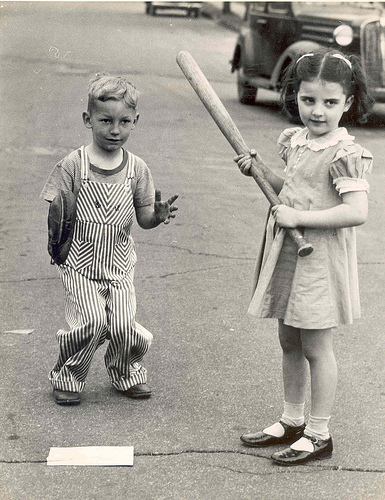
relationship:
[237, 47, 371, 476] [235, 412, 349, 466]
girl wearing shoes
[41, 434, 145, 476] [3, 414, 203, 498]
paper on pavement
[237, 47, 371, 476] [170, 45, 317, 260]
girl holding bat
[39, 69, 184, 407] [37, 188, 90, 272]
boy holding mitt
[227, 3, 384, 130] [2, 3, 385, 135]
truck in background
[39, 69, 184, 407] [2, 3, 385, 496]
boy in street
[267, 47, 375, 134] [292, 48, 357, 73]
hair has barrettes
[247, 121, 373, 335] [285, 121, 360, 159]
dress with collar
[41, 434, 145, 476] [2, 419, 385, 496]
paper on ground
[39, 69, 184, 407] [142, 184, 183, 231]
boy has hand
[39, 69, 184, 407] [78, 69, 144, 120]
boy has hair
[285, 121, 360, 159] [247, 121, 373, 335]
collar on dress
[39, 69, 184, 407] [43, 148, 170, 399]
boy wearing coveralls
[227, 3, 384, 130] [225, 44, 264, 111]
car has tires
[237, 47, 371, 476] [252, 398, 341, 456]
girl wears socks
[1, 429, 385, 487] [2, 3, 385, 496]
crack in road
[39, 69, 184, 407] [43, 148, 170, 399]
dungarees wearing dungarees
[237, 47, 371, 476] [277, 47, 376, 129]
girl has pigtails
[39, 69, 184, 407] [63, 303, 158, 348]
boy has knees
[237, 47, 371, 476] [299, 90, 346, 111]
girl has eyes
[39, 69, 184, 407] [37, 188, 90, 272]
boy wearing glove